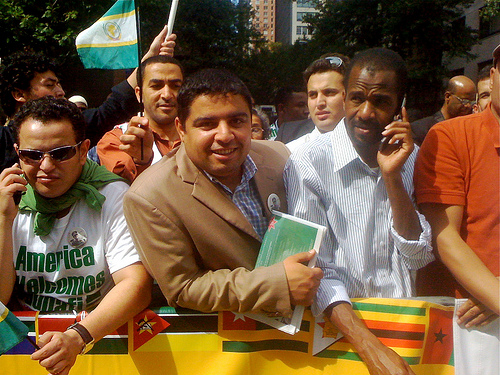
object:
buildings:
[292, 0, 325, 42]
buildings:
[247, 0, 278, 55]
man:
[285, 51, 435, 375]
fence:
[0, 296, 499, 374]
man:
[405, 75, 478, 145]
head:
[442, 75, 477, 115]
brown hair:
[176, 68, 253, 134]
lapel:
[171, 139, 279, 243]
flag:
[217, 310, 309, 352]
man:
[122, 69, 296, 318]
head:
[174, 71, 252, 177]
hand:
[243, 208, 327, 333]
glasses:
[14, 138, 84, 163]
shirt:
[0, 158, 142, 316]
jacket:
[124, 139, 290, 310]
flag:
[74, 1, 139, 70]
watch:
[67, 322, 94, 346]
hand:
[376, 107, 414, 175]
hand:
[455, 277, 500, 330]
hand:
[278, 250, 323, 308]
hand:
[119, 117, 152, 164]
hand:
[30, 330, 79, 373]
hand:
[0, 166, 27, 215]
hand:
[146, 20, 176, 60]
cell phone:
[379, 92, 408, 153]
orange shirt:
[413, 100, 498, 297]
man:
[413, 43, 500, 332]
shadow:
[409, 126, 438, 253]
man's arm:
[378, 134, 434, 275]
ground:
[376, 144, 410, 182]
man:
[2, 97, 150, 375]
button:
[266, 192, 280, 213]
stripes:
[352, 184, 360, 255]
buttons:
[379, 240, 386, 247]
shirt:
[286, 115, 433, 319]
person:
[124, 67, 323, 316]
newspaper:
[247, 209, 323, 336]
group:
[0, 23, 500, 375]